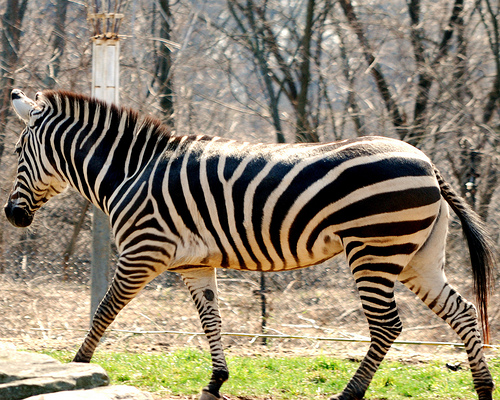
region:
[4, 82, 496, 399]
A zebra in captivity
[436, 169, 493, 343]
Black and white tail of zebra.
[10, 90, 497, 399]
Zebra in captivity walking about zoo.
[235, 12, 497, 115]
Trees bare of leaves outside enclosure.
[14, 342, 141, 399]
Gray flat stones inside of zoo.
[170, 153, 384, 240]
Unique black and white pattern on zebra.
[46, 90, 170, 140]
Zebra's black and white mane.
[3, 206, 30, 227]
Black snout of zebra in zoo.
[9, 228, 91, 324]
Section of metal fencing enclosure.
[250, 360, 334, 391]
Green grass growing inside of zoo enclosure.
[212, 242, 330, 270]
Underbelly of zebra inside of zoo.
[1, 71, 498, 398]
zebra walking in habitat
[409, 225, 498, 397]
zebra's right rear leg bent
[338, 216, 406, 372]
faded black stripes between dark stripes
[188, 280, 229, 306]
black spot on zebra's right front leg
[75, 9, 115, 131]
metal fence pole bordering habitat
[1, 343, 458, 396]
sun glistening off of grass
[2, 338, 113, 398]
flat rock in zebra habitat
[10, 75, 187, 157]
zebra mane with black and white stripes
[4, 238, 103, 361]
chain link fence bordering habitat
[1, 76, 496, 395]
zebra looking away from camera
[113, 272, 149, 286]
black stripe on zebra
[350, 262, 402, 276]
black stripe on zebra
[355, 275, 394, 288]
black stripe on zebra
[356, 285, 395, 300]
black stripe on zebra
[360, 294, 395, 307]
black stripe on zebra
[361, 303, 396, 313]
black stripe on zebra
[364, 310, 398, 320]
black stripe on zebra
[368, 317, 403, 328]
black stripe on zebra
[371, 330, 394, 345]
black stripe on zebra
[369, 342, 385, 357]
black stripe on zebra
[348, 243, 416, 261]
black stripe on zebra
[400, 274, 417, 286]
black stripe on zebra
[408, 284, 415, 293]
black stripe on zebra